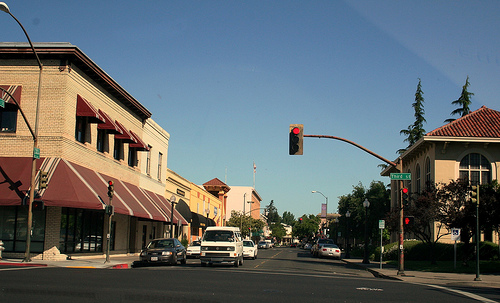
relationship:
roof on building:
[379, 103, 499, 178] [378, 104, 498, 245]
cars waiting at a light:
[200, 226, 246, 268] [293, 126, 301, 133]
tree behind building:
[377, 80, 428, 167] [378, 104, 498, 245]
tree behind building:
[446, 70, 474, 121] [378, 104, 498, 245]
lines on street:
[255, 251, 284, 269] [0, 242, 497, 302]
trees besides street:
[331, 181, 401, 260] [0, 241, 455, 301]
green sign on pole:
[390, 173, 413, 181] [397, 152, 404, 274]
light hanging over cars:
[293, 126, 301, 133] [103, 174, 253, 280]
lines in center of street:
[253, 247, 288, 278] [161, 235, 376, 300]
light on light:
[280, 129, 318, 142] [293, 126, 301, 133]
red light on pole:
[402, 188, 409, 192] [396, 158, 406, 275]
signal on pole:
[401, 215, 413, 234] [391, 167, 410, 272]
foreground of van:
[5, 204, 492, 296] [199, 225, 245, 267]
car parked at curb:
[135, 232, 187, 267] [58, 250, 146, 272]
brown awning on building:
[0, 155, 190, 226] [41, 42, 167, 259]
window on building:
[447, 142, 499, 199] [378, 104, 498, 245]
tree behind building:
[375, 80, 428, 171] [378, 104, 498, 245]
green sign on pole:
[390, 173, 413, 181] [394, 154, 403, 275]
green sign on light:
[390, 173, 413, 181] [293, 126, 301, 133]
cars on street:
[200, 226, 246, 268] [0, 242, 497, 302]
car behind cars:
[243, 236, 259, 261] [200, 226, 246, 268]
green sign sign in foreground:
[390, 173, 413, 181] [384, 136, 415, 228]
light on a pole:
[293, 126, 301, 133] [301, 134, 406, 274]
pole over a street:
[301, 134, 406, 274] [250, 212, 362, 295]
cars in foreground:
[200, 226, 246, 268] [5, 204, 492, 296]